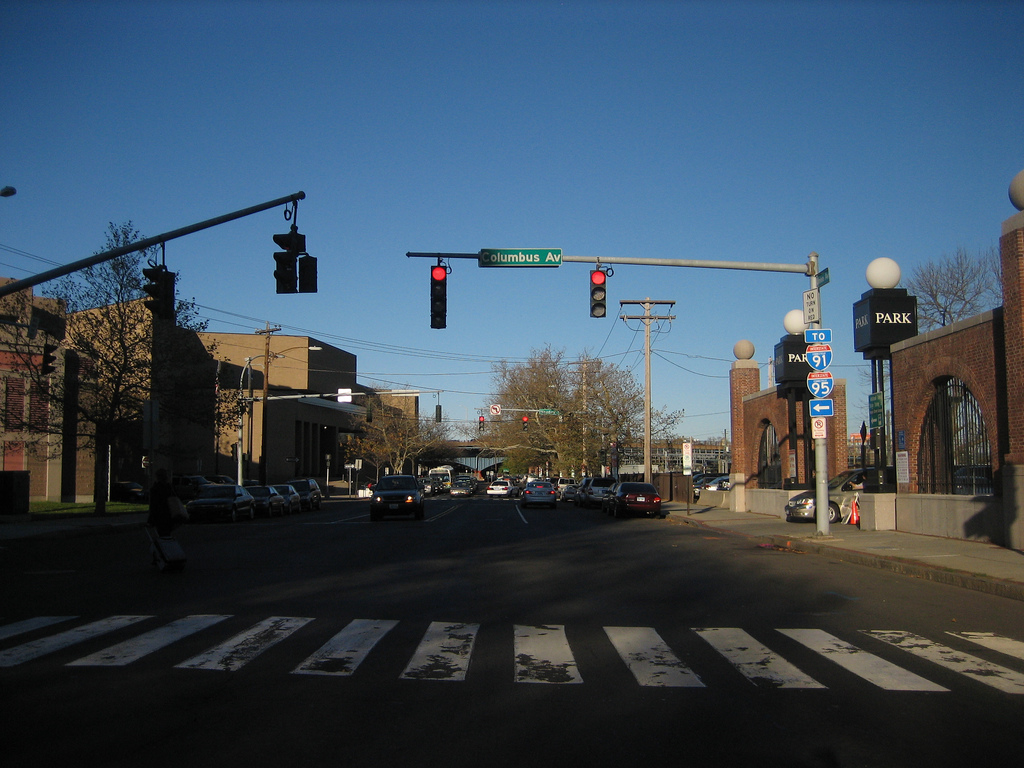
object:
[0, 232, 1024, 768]
outdoors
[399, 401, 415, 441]
wall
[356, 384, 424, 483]
building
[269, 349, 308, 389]
wall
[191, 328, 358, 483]
building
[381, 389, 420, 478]
building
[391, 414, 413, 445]
wall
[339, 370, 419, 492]
wall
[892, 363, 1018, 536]
glass